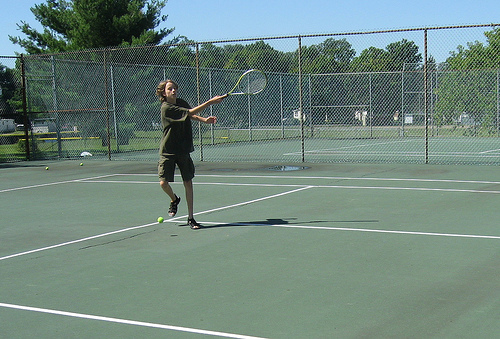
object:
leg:
[158, 155, 176, 201]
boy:
[153, 80, 223, 230]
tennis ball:
[45, 167, 50, 170]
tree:
[3, 0, 183, 56]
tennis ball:
[80, 163, 84, 166]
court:
[0, 164, 500, 339]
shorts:
[157, 152, 196, 182]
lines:
[0, 303, 258, 339]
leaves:
[7, 0, 176, 51]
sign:
[0, 167, 500, 339]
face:
[165, 82, 179, 101]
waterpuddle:
[268, 162, 305, 173]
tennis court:
[105, 135, 497, 172]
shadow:
[177, 217, 378, 229]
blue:
[0, 0, 500, 46]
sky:
[0, 0, 492, 39]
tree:
[34, 3, 152, 128]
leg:
[178, 158, 195, 218]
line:
[311, 185, 499, 196]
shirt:
[158, 97, 195, 157]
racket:
[217, 68, 268, 99]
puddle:
[208, 164, 311, 171]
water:
[268, 166, 310, 172]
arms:
[187, 94, 223, 116]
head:
[155, 80, 179, 102]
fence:
[19, 20, 498, 166]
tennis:
[157, 217, 164, 224]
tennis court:
[0, 160, 497, 339]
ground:
[0, 162, 500, 338]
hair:
[155, 79, 178, 104]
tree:
[9, 0, 189, 155]